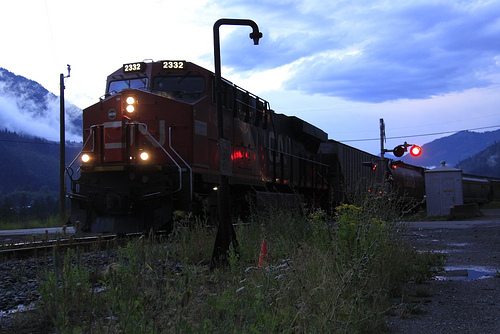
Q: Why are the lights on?
A: It is dusk.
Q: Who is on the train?
A: Passengers.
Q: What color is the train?
A: Black.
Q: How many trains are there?
A: One.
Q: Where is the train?
A: At a crossing.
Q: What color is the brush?
A: Green.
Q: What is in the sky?
A: Clouds.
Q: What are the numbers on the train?
A: 2332.